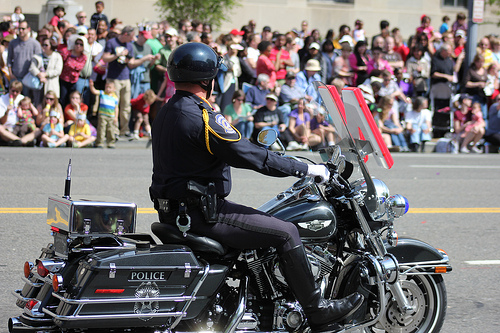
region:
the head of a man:
[162, 37, 237, 101]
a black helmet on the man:
[164, 37, 236, 84]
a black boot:
[273, 239, 365, 331]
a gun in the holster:
[182, 176, 221, 226]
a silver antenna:
[58, 16, 102, 197]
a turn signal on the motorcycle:
[16, 255, 32, 279]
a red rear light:
[31, 253, 54, 278]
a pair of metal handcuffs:
[171, 207, 195, 242]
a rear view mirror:
[253, 125, 280, 148]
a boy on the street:
[83, 75, 124, 150]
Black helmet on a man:
[146, 33, 259, 105]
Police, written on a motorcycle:
[48, 228, 217, 296]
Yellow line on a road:
[3, 188, 78, 235]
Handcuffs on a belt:
[161, 195, 226, 235]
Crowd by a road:
[16, 13, 322, 152]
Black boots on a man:
[253, 223, 390, 331]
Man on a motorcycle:
[33, 46, 413, 311]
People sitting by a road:
[41, 107, 139, 144]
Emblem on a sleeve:
[196, 78, 266, 155]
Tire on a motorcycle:
[338, 233, 458, 314]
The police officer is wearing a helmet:
[149, 32, 227, 93]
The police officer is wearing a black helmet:
[156, 27, 243, 101]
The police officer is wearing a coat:
[121, 80, 343, 210]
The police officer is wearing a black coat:
[125, 85, 320, 185]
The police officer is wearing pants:
[152, 176, 288, 296]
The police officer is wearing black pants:
[196, 191, 306, 277]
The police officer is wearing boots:
[265, 232, 379, 325]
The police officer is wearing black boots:
[272, 238, 383, 332]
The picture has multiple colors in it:
[9, 8, 491, 328]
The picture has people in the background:
[6, 8, 498, 169]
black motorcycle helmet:
[155, 29, 245, 121]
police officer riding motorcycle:
[23, 31, 474, 329]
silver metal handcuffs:
[161, 193, 206, 252]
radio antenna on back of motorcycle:
[48, 3, 93, 212]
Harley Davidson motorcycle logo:
[289, 210, 339, 249]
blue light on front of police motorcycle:
[340, 163, 437, 253]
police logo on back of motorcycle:
[92, 254, 177, 331]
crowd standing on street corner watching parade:
[10, 3, 163, 163]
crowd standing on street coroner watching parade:
[369, 15, 494, 136]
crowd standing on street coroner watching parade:
[225, 21, 322, 153]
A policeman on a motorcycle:
[156, 64, 302, 265]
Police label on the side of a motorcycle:
[122, 259, 177, 330]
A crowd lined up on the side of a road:
[16, 8, 145, 141]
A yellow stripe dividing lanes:
[407, 187, 487, 227]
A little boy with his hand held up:
[77, 66, 137, 142]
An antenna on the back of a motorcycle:
[53, 154, 102, 207]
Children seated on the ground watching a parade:
[24, 103, 95, 151]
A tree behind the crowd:
[164, 5, 246, 35]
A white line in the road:
[412, 156, 481, 183]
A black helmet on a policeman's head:
[164, 29, 229, 94]